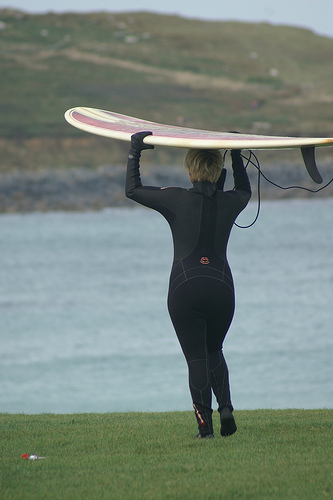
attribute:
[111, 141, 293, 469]
lady — carrying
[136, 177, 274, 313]
suit — tight, black, wet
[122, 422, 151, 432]
grass — green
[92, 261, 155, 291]
water — blue, spanning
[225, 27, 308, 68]
hill — small, rock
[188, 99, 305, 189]
surfboard — white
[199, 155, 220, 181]
head — female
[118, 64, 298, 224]
board — string, short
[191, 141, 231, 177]
hair — brown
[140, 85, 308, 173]
surfer — walking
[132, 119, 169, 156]
glove — black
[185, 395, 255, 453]
shoe — water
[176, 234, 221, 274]
item — red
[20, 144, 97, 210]
wall — blurry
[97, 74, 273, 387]
person — holding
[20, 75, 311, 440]
scene — happening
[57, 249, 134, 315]
ocean — blue